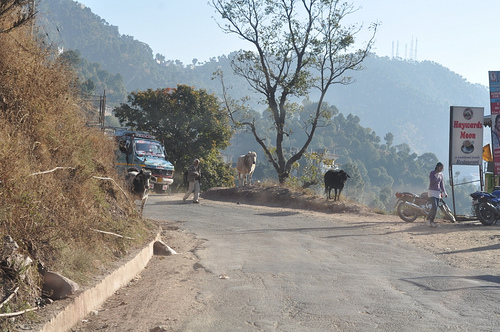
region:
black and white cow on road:
[122, 167, 160, 214]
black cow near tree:
[323, 165, 352, 201]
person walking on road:
[179, 153, 210, 201]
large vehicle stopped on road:
[111, 125, 177, 195]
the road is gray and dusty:
[66, 192, 499, 329]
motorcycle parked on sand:
[393, 188, 444, 224]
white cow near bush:
[235, 150, 262, 180]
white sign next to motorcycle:
[447, 106, 492, 223]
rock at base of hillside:
[41, 267, 83, 297]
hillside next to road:
[1, 10, 165, 328]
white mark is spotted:
[221, 260, 228, 282]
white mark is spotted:
[219, 267, 226, 280]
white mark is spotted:
[219, 265, 229, 288]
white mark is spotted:
[217, 260, 232, 303]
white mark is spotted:
[222, 275, 234, 294]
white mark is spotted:
[209, 260, 244, 297]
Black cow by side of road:
[317, 168, 349, 201]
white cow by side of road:
[230, 147, 258, 182]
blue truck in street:
[107, 126, 177, 193]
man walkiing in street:
[183, 156, 205, 201]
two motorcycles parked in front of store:
[390, 182, 498, 233]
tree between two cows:
[200, 0, 382, 195]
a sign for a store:
[450, 105, 483, 167]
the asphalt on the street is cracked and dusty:
[47, 190, 496, 329]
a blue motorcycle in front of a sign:
[467, 186, 498, 229]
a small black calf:
[320, 162, 351, 203]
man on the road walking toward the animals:
[181, 151, 205, 211]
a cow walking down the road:
[121, 163, 162, 205]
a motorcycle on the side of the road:
[391, 183, 460, 228]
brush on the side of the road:
[9, 67, 121, 251]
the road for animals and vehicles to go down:
[173, 207, 358, 325]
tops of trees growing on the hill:
[339, 116, 393, 163]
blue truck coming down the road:
[116, 132, 176, 188]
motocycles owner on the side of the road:
[429, 166, 448, 221]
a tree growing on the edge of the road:
[260, 44, 311, 187]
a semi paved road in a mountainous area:
[187, 241, 479, 323]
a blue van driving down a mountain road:
[114, 125, 171, 189]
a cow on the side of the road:
[126, 167, 157, 210]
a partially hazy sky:
[150, 6, 205, 36]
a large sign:
[450, 101, 485, 221]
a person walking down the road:
[181, 155, 201, 205]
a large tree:
[254, 3, 326, 193]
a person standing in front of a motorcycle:
[398, 159, 458, 230]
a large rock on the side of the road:
[156, 237, 177, 259]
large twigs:
[0, 279, 42, 323]